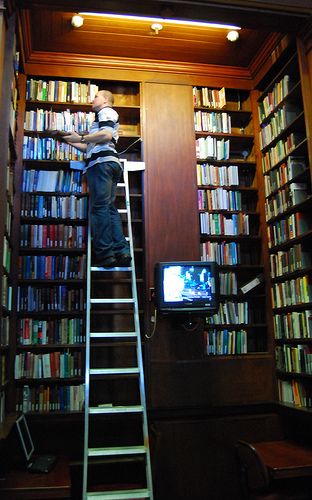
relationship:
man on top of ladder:
[55, 89, 135, 270] [80, 156, 155, 498]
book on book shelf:
[64, 77, 75, 106] [21, 73, 144, 105]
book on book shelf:
[216, 85, 230, 109] [186, 81, 253, 112]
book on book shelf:
[227, 188, 239, 213] [195, 185, 264, 214]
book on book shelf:
[227, 240, 241, 267] [198, 236, 267, 270]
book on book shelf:
[232, 270, 270, 300] [215, 267, 268, 301]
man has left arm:
[55, 89, 135, 270] [61, 109, 119, 147]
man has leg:
[55, 89, 135, 270] [81, 161, 121, 272]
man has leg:
[55, 89, 135, 270] [104, 159, 136, 269]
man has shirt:
[55, 89, 135, 270] [79, 106, 126, 177]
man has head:
[55, 89, 135, 270] [87, 90, 117, 109]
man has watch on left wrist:
[55, 89, 135, 270] [77, 132, 89, 147]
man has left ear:
[55, 89, 135, 270] [101, 95, 112, 105]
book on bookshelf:
[50, 349, 66, 382] [8, 347, 90, 385]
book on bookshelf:
[194, 164, 204, 189] [193, 161, 258, 191]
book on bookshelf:
[222, 149, 223, 150] [189, 134, 258, 159]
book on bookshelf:
[217, 112, 231, 137] [189, 110, 259, 139]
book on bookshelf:
[42, 222, 48, 251] [16, 218, 148, 255]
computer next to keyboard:
[13, 413, 58, 473] [25, 449, 59, 475]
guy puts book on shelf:
[55, 89, 135, 270] [21, 99, 146, 138]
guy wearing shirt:
[55, 89, 135, 270] [79, 106, 126, 177]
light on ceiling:
[68, 12, 84, 31] [0, 2, 309, 97]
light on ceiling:
[142, 14, 168, 39] [0, 2, 309, 97]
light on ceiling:
[225, 28, 240, 42] [0, 2, 309, 97]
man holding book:
[55, 89, 135, 270] [46, 126, 75, 143]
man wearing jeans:
[55, 89, 135, 270] [81, 161, 121, 272]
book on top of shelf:
[231, 330, 245, 354] [199, 326, 271, 359]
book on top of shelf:
[40, 386, 54, 418] [5, 379, 129, 417]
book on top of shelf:
[302, 277, 310, 310] [271, 275, 311, 315]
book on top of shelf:
[29, 168, 43, 197] [12, 160, 153, 201]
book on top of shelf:
[35, 194, 45, 215] [6, 188, 150, 225]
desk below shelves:
[242, 438, 311, 499] [186, 47, 311, 417]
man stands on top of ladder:
[55, 89, 135, 270] [80, 156, 155, 498]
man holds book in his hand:
[55, 89, 135, 270] [57, 123, 87, 144]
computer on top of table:
[0, 409, 64, 476] [4, 444, 76, 499]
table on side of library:
[2, 98, 76, 496] [4, 1, 311, 500]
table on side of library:
[4, 444, 76, 499] [4, 1, 311, 500]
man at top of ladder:
[55, 89, 135, 270] [80, 156, 155, 498]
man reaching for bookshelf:
[55, 89, 135, 270] [21, 99, 146, 138]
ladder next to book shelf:
[80, 156, 155, 498] [21, 73, 144, 105]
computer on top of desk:
[0, 409, 64, 476] [4, 444, 76, 499]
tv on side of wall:
[151, 260, 223, 318] [142, 77, 225, 431]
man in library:
[55, 89, 135, 270] [4, 1, 311, 500]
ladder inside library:
[80, 156, 155, 498] [4, 1, 311, 500]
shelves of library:
[4, 1, 311, 500] [4, 1, 311, 500]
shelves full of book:
[4, 1, 311, 500] [1, 74, 311, 412]